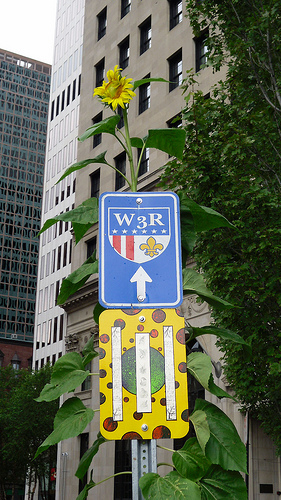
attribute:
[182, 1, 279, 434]
tree — large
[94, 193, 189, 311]
sign — blue, white, colorful, rectangular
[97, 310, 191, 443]
sign — yellow, red, green, white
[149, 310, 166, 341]
circles — red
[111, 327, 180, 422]
stripes — white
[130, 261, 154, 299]
arrow — white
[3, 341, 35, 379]
bricks — red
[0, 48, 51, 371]
building — gray, tall, large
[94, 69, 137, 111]
flower — yellow, tall, sunflower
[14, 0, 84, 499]
building — white, tall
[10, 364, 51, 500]
tree — small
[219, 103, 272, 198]
leaves — green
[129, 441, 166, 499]
pole — metal, silver